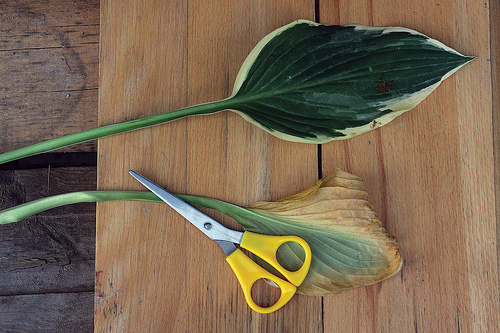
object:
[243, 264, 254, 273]
part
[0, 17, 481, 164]
leaf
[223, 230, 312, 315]
handle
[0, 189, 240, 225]
stem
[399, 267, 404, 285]
screw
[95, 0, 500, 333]
board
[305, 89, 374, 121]
water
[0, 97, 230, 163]
stem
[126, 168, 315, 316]
scissors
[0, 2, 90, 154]
spot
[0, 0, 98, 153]
plank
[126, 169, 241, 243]
edge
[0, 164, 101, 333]
wall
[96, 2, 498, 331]
table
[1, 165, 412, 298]
leaf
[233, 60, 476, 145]
edging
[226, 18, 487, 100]
edging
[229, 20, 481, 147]
leaves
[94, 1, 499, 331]
wood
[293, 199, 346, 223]
brown spot